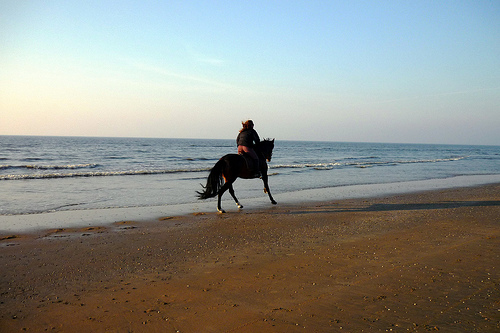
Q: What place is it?
A: It is a beach.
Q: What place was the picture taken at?
A: It was taken at the beach.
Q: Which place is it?
A: It is a beach.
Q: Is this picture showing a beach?
A: Yes, it is showing a beach.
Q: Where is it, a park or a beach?
A: It is a beach.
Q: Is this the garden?
A: No, it is the beach.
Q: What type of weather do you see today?
A: It is cloudy.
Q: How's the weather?
A: It is cloudy.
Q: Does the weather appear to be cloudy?
A: Yes, it is cloudy.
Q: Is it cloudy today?
A: Yes, it is cloudy.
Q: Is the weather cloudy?
A: Yes, it is cloudy.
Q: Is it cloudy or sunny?
A: It is cloudy.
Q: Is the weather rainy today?
A: No, it is cloudy.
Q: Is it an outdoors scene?
A: Yes, it is outdoors.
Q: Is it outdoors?
A: Yes, it is outdoors.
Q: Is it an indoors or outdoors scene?
A: It is outdoors.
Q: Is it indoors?
A: No, it is outdoors.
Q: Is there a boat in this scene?
A: No, there are no boats.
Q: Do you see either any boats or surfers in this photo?
A: No, there are no boats or surfers.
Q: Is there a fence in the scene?
A: No, there are no fences.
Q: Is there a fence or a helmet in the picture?
A: No, there are no fences or helmets.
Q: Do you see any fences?
A: No, there are no fences.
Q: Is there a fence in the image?
A: No, there are no fences.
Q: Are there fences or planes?
A: No, there are no fences or planes.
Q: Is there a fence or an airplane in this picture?
A: No, there are no fences or airplanes.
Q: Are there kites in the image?
A: No, there are no kites.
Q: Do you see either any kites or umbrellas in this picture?
A: No, there are no kites or umbrellas.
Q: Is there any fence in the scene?
A: No, there are no fences.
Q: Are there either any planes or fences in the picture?
A: No, there are no fences or planes.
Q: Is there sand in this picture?
A: Yes, there is sand.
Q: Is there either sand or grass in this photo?
A: Yes, there is sand.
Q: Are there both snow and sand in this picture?
A: No, there is sand but no snow.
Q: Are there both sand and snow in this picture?
A: No, there is sand but no snow.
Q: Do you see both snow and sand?
A: No, there is sand but no snow.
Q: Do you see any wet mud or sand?
A: Yes, there is wet sand.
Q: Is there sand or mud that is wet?
A: Yes, the sand is wet.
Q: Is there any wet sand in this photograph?
A: Yes, there is wet sand.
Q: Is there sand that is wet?
A: Yes, there is sand that is wet.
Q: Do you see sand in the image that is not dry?
A: Yes, there is wet sand.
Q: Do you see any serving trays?
A: No, there are no serving trays.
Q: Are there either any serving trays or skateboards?
A: No, there are no serving trays or skateboards.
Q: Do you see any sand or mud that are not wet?
A: No, there is sand but it is wet.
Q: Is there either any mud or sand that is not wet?
A: No, there is sand but it is wet.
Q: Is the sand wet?
A: Yes, the sand is wet.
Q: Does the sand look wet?
A: Yes, the sand is wet.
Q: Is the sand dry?
A: No, the sand is wet.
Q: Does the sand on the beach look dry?
A: No, the sand is wet.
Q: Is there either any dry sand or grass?
A: No, there is sand but it is wet.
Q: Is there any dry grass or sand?
A: No, there is sand but it is wet.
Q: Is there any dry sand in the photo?
A: No, there is sand but it is wet.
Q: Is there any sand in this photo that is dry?
A: No, there is sand but it is wet.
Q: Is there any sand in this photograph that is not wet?
A: No, there is sand but it is wet.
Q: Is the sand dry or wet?
A: The sand is wet.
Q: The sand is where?
A: The sand is on the beach.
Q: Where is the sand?
A: The sand is on the beach.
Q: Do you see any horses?
A: Yes, there is a horse.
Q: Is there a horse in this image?
A: Yes, there is a horse.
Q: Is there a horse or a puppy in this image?
A: Yes, there is a horse.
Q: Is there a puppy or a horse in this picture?
A: Yes, there is a horse.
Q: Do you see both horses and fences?
A: No, there is a horse but no fences.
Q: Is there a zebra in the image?
A: No, there are no zebras.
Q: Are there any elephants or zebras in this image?
A: No, there are no zebras or elephants.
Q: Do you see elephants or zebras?
A: No, there are no zebras or elephants.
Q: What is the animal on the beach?
A: The animal is a horse.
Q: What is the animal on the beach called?
A: The animal is a horse.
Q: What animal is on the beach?
A: The animal is a horse.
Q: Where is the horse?
A: The horse is on the beach.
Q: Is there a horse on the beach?
A: Yes, there is a horse on the beach.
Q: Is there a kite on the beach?
A: No, there is a horse on the beach.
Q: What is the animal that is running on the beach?
A: The animal is a horse.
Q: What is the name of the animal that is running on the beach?
A: The animal is a horse.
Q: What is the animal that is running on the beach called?
A: The animal is a horse.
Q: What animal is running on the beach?
A: The animal is a horse.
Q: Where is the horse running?
A: The horse is running on the beach.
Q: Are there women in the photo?
A: Yes, there is a woman.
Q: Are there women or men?
A: Yes, there is a woman.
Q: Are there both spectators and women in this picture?
A: No, there is a woman but no spectators.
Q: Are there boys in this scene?
A: No, there are no boys.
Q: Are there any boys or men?
A: No, there are no boys or men.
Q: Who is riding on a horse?
A: The woman is riding on a horse.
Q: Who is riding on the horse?
A: The woman is riding on a horse.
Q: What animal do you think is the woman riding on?
A: The woman is riding on a horse.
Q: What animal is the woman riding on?
A: The woman is riding on a horse.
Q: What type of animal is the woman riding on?
A: The woman is riding on a horse.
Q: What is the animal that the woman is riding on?
A: The animal is a horse.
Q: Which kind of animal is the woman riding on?
A: The woman is riding on a horse.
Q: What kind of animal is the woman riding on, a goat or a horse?
A: The woman is riding on a horse.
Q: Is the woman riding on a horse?
A: Yes, the woman is riding on a horse.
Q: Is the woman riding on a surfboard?
A: No, the woman is riding on a horse.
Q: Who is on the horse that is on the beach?
A: The woman is on the horse.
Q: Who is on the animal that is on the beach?
A: The woman is on the horse.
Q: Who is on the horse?
A: The woman is on the horse.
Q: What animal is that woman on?
A: The woman is on the horse.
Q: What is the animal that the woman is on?
A: The animal is a horse.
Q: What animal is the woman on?
A: The woman is on the horse.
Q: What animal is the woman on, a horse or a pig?
A: The woman is on a horse.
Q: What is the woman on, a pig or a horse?
A: The woman is on a horse.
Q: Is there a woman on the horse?
A: Yes, there is a woman on the horse.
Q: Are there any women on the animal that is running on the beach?
A: Yes, there is a woman on the horse.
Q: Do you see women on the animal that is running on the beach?
A: Yes, there is a woman on the horse.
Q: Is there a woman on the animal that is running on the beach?
A: Yes, there is a woman on the horse.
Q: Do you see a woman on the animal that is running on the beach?
A: Yes, there is a woman on the horse.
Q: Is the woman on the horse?
A: Yes, the woman is on the horse.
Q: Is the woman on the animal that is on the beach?
A: Yes, the woman is on the horse.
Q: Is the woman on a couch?
A: No, the woman is on the horse.